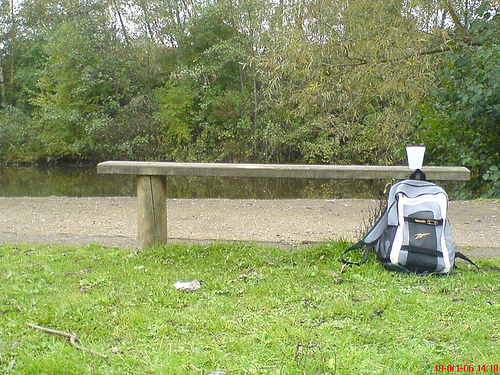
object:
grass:
[0, 239, 493, 372]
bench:
[95, 153, 470, 256]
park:
[0, 12, 499, 375]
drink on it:
[403, 145, 428, 170]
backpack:
[340, 169, 480, 277]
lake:
[0, 155, 487, 201]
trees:
[0, 0, 499, 166]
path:
[0, 192, 498, 244]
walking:
[0, 192, 498, 261]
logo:
[414, 232, 436, 242]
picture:
[5, 7, 499, 375]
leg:
[133, 174, 166, 251]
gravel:
[0, 198, 499, 245]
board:
[94, 160, 471, 183]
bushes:
[414, 4, 499, 192]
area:
[0, 234, 499, 375]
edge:
[4, 194, 371, 203]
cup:
[403, 145, 425, 172]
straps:
[341, 188, 389, 265]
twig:
[23, 322, 111, 364]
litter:
[167, 279, 202, 292]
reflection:
[44, 164, 126, 187]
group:
[6, 10, 478, 167]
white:
[408, 151, 416, 159]